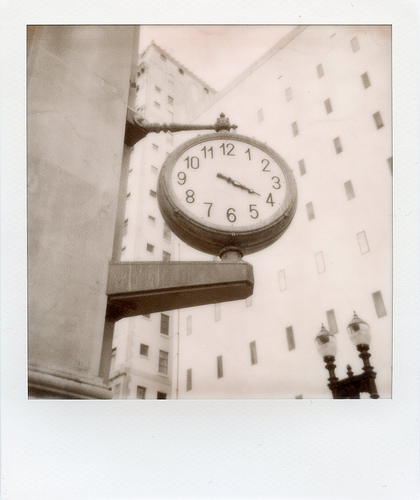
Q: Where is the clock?
A: On the building.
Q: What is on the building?
A: Clock.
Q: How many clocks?
A: 1.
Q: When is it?
A: 4:20.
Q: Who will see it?
A: People.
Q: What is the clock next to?
A: Buildings.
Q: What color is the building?
A: White.